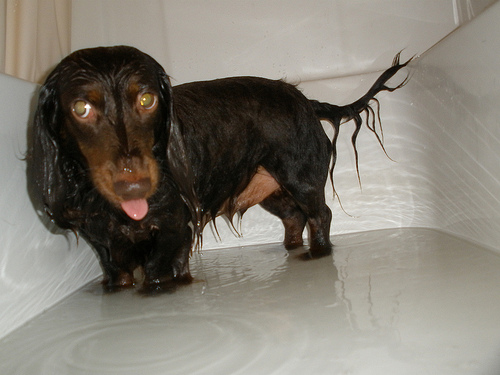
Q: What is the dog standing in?
A: A tub of water.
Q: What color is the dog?
A: Brown.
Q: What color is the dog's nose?
A: Brown.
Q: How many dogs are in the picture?
A: One.